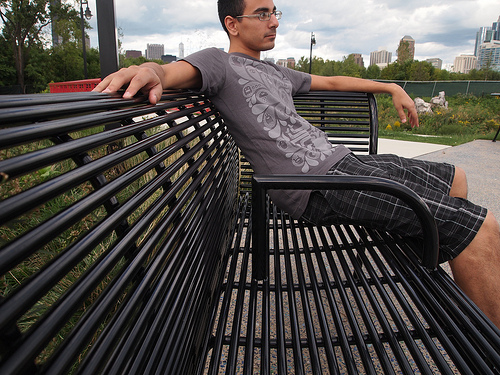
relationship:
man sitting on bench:
[92, 1, 499, 300] [0, 84, 498, 372]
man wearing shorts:
[92, 1, 499, 300] [310, 132, 493, 275]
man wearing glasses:
[92, 1, 499, 300] [235, 7, 284, 26]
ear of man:
[221, 14, 241, 41] [92, 1, 499, 300]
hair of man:
[216, 1, 252, 35] [92, 1, 499, 300]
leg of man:
[456, 214, 500, 307] [92, 1, 499, 300]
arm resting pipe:
[102, 37, 199, 117] [4, 81, 125, 127]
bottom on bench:
[195, 192, 500, 375] [0, 84, 498, 372]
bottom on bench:
[220, 200, 465, 366] [0, 84, 498, 372]